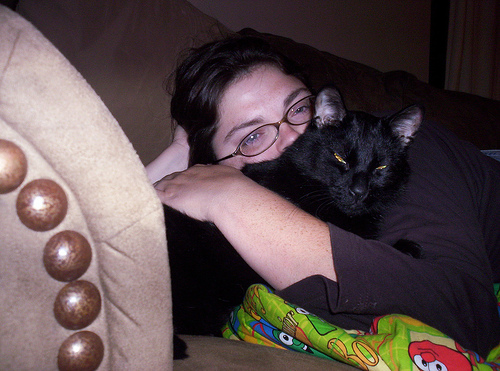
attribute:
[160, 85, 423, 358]
cat — sleeping, squinting, black, resting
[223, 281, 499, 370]
blanket — veggie-tales, colorful, angry-birds, green, white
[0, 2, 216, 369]
couch — light, tan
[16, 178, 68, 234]
rivet — gold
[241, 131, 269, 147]
right-eye — blue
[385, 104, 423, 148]
left-ear — pointed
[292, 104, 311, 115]
left-eye — open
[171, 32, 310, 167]
hair — dark, black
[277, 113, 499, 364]
shirt — black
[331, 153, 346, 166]
eye — yellow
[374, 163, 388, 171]
eye — yellow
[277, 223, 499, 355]
sleeve — long